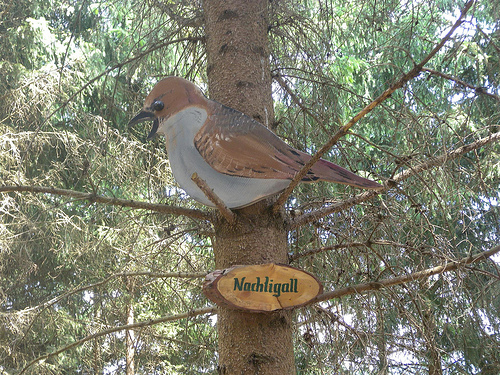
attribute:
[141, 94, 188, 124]
eye — black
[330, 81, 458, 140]
tree — pine, green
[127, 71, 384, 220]
bird — painted, white, wooden, angry, fake, brown, carved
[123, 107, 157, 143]
beak — open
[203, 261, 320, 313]
sign — wooden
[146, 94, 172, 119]
eyes — black, beady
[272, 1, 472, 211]
branch — thin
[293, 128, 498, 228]
branch — thin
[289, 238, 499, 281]
branch — thin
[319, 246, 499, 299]
branch — thin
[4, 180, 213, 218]
branch — thin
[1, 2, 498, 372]
tree — pine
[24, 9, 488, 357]
tree — old, pine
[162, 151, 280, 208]
belly — white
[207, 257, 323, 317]
sign — wood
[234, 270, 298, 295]
writing — green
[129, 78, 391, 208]
bird — fake, wooden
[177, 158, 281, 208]
belly — white